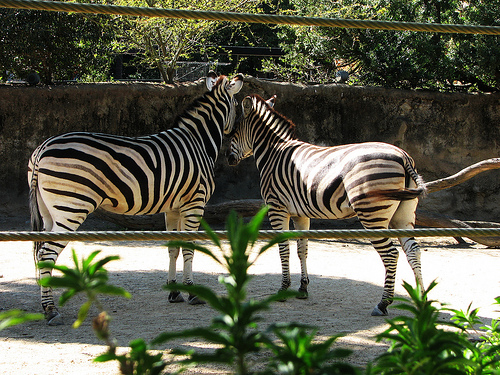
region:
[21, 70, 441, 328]
Two zebras standing together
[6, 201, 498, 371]
Green plants in front of metal fence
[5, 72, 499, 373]
Zebras standing on dry rocky ground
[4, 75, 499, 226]
Rock wall with moss growing on it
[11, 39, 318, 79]
Metal fence with thin wires at top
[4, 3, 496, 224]
Line of tree behind rock wall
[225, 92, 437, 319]
Zebra with its tail in motion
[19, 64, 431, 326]
Two zebras with heads close together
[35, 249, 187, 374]
Tall dark green leafty plant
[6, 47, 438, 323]
Two zebras being held in captivity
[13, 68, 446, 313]
Two zebras being held in captivity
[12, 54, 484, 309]
Two zebras being held in captivity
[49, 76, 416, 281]
Two zebras being held in captivity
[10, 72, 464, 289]
Two zebras being held in captivity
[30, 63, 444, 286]
Two zebras being held in captivity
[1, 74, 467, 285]
Two zebras being held in captivity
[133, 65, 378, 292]
Two zebras being held in captivity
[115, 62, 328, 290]
Two zebras being held in captivity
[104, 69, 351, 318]
Two zebras being held in captivity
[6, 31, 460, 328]
two zebras in the zoo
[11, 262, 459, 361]
shadows on the ground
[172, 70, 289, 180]
two zebra heads touching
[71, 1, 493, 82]
a long rope above the zebras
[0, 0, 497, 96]
trees above the zebras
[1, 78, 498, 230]
a stone concrete wall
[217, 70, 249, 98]
a zebras right ear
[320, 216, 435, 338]
a zebras hind legs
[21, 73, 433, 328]
Two zebras at a zoo.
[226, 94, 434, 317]
A zebra at a zoo.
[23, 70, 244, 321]
A zebra in an enclosure.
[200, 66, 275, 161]
Two zebra heads.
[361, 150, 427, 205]
A swishing zebra tail.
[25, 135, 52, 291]
A long zebra tail.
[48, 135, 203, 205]
A zebra's stripes.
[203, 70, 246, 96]
A zebra's ears.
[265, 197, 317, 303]
Front legs of a zebra.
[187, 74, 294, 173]
Two zebras snuggling.